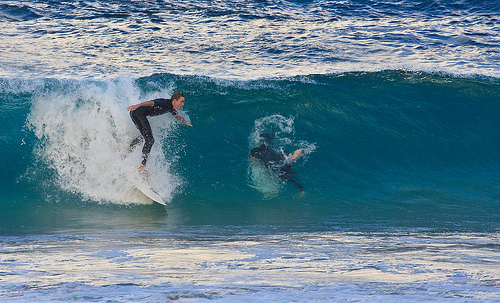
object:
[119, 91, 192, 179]
surfer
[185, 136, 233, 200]
water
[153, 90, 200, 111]
right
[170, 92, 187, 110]
head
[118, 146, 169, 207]
board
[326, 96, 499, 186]
blue ocean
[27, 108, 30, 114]
ripples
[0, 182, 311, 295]
foreground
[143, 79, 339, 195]
being in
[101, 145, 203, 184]
surfing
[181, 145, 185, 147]
wave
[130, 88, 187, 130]
outstretched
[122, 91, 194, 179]
man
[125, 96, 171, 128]
side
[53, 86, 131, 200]
white water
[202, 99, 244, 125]
section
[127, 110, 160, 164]
rashguard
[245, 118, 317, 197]
person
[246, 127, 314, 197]
swimmer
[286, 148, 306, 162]
foot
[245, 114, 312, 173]
down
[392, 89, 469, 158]
greenish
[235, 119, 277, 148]
thing